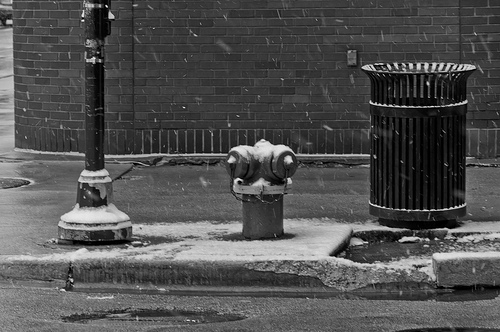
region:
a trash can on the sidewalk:
[360, 60, 477, 223]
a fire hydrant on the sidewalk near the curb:
[224, 138, 299, 239]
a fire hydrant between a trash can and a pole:
[226, 136, 298, 236]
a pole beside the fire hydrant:
[57, 2, 133, 243]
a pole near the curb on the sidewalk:
[57, 0, 132, 241]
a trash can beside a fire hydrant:
[360, 59, 476, 223]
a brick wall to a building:
[12, 2, 499, 154]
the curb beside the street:
[2, 251, 499, 283]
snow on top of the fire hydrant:
[229, 137, 291, 160]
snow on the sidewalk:
[134, 221, 329, 258]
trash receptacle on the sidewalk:
[346, 53, 476, 225]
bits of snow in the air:
[123, 4, 292, 181]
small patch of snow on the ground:
[96, 199, 360, 281]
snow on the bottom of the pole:
[60, 170, 131, 228]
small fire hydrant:
[221, 128, 308, 245]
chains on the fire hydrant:
[223, 181, 295, 208]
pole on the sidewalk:
[52, 4, 143, 249]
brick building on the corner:
[8, 6, 499, 175]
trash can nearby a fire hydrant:
[193, 46, 499, 248]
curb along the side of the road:
[0, 243, 499, 301]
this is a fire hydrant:
[206, 133, 311, 237]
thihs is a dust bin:
[352, 38, 482, 230]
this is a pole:
[58, 0, 143, 252]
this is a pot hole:
[56, 297, 251, 329]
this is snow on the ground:
[145, 201, 245, 286]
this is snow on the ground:
[290, 215, 340, 280]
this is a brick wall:
[18, 1, 490, 151]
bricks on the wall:
[160, 35, 200, 62]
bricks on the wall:
[252, 55, 282, 92]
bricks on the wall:
[159, 85, 197, 136]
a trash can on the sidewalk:
[335, 22, 499, 258]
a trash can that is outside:
[326, 23, 499, 260]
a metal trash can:
[348, 28, 495, 238]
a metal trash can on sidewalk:
[307, 43, 497, 265]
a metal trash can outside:
[312, 44, 494, 272]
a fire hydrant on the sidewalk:
[211, 98, 311, 251]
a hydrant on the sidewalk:
[223, 98, 318, 251]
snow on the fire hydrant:
[211, 103, 318, 261]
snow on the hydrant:
[182, 113, 293, 254]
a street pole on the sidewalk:
[29, 5, 193, 291]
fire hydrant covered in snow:
[221, 134, 301, 246]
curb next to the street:
[1, 246, 497, 294]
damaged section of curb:
[236, 250, 451, 299]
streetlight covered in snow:
[52, 0, 140, 252]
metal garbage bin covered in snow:
[353, 55, 480, 235]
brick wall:
[8, 2, 496, 163]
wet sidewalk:
[2, 139, 499, 270]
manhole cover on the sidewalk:
[1, 170, 37, 195]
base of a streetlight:
[50, 165, 137, 248]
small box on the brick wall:
[343, 45, 359, 70]